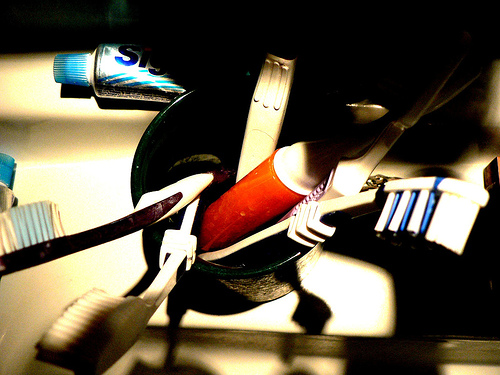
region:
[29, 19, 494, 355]
toothbrushes in green cup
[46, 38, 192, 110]
toothpaste tube on counter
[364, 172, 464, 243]
blue and white bristles on toothbrush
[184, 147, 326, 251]
orange handle in cup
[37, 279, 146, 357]
white bristles on brush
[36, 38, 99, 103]
blue cap on toothpaste tube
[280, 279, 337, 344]
toothbrush shadow on counter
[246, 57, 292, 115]
design on toothbrush handle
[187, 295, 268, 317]
shadow from green cup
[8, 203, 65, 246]
light blue bristles on toothbrush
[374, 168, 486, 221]
blue and white toothbrush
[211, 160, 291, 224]
orange handle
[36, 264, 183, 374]
this is a toothbrush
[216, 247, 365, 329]
this is a toothbrush holder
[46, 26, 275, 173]
a container of toothpaste in the back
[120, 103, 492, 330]
six toothbrush handles in the picture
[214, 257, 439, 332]
toothbrush holder is green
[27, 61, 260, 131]
toothpaste tube is blue and white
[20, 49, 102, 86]
cap to tube of toothpaste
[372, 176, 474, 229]
bristles of a toothbrush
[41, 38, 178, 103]
Top half of toothpaste.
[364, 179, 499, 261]
Brush of a toothbrush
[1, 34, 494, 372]
A cup holding several toothbrushes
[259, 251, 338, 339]
Shadow of a toothbrush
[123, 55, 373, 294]
Handles of toothbrushes sitting in a cup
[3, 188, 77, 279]
Blue and white toothbrush brush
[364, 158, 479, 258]
Blue and white striped toothbrush brush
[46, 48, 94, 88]
Blue cap on toothpaste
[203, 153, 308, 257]
Orange handle on toothbrush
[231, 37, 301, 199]
White handle of toothbrush sitting in cup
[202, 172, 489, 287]
the toothbrush is white and blue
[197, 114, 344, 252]
the object is red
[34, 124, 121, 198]
the counter is white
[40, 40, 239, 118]
the toothpaste is blue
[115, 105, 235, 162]
the holder is black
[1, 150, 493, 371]
there are many toothbrushes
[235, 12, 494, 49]
the area is dark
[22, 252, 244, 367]
the toothbrush is facing left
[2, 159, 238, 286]
the toothbrush is white and purple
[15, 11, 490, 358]
the toothbrushes are in the cup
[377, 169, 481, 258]
The white-and-blue head of a toothbrush.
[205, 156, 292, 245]
A toothbrush's orange handle.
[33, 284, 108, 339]
The white bristles of a toothbrush.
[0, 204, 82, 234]
Blue bristles with white bristles at either end.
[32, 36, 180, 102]
A tube of toothpaste.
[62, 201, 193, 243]
A toothbrush's purple neck.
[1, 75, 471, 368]
A mug full of toothbrushes.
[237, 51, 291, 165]
A toothbrush's white body.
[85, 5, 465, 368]
Toothbrushes standing up in a mug.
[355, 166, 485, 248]
A toothbrush head with alternating blue and white bristles.